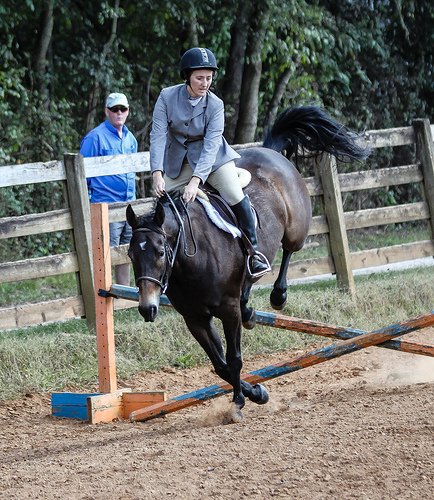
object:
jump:
[107, 284, 433, 429]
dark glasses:
[105, 106, 129, 112]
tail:
[263, 105, 374, 175]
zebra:
[125, 105, 374, 426]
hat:
[179, 47, 218, 79]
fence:
[0, 118, 433, 337]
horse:
[124, 104, 372, 426]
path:
[233, 430, 377, 492]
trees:
[140, 1, 402, 126]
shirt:
[76, 120, 138, 203]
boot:
[198, 186, 256, 258]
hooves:
[252, 383, 268, 406]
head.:
[125, 202, 172, 324]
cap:
[105, 92, 129, 108]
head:
[103, 92, 130, 129]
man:
[78, 91, 139, 287]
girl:
[150, 46, 267, 272]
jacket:
[149, 82, 242, 185]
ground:
[0, 313, 419, 498]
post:
[54, 202, 433, 426]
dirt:
[2, 346, 420, 484]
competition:
[126, 47, 373, 426]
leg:
[207, 159, 259, 256]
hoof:
[222, 404, 243, 425]